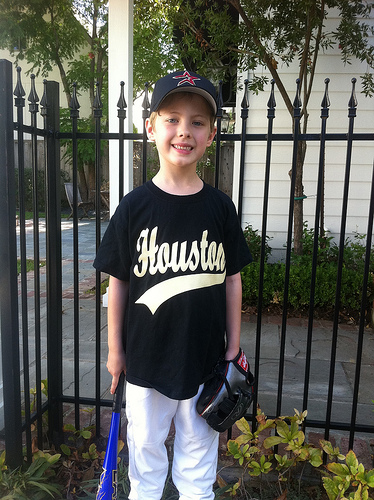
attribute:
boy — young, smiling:
[93, 71, 247, 498]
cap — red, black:
[149, 69, 222, 124]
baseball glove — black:
[194, 347, 252, 431]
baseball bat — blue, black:
[95, 373, 124, 500]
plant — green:
[215, 406, 373, 499]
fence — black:
[1, 62, 373, 471]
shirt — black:
[94, 178, 251, 398]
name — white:
[133, 229, 226, 314]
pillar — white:
[109, 1, 134, 221]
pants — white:
[126, 379, 219, 499]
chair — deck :
[65, 179, 92, 220]